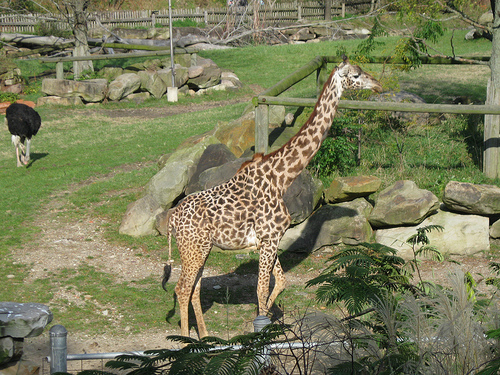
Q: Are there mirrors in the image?
A: No, there are no mirrors.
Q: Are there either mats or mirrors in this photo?
A: No, there are no mirrors or mats.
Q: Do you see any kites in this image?
A: No, there are no kites.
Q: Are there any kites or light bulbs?
A: No, there are no kites or light bulbs.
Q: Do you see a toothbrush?
A: No, there are no toothbrushes.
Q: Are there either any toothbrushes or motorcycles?
A: No, there are no toothbrushes or motorcycles.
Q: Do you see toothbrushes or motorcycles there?
A: No, there are no toothbrushes or motorcycles.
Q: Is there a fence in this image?
A: Yes, there is a fence.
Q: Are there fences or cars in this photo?
A: Yes, there is a fence.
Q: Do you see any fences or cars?
A: Yes, there is a fence.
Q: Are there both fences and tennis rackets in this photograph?
A: No, there is a fence but no rackets.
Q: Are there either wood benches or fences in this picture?
A: Yes, there is a wood fence.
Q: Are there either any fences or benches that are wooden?
A: Yes, the fence is wooden.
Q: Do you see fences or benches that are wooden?
A: Yes, the fence is wooden.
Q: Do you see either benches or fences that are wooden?
A: Yes, the fence is wooden.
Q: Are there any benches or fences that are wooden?
A: Yes, the fence is wooden.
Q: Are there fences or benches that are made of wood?
A: Yes, the fence is made of wood.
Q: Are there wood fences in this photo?
A: Yes, there is a wood fence.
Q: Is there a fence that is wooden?
A: Yes, there is a fence that is wooden.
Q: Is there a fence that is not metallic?
A: Yes, there is a wooden fence.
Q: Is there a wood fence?
A: Yes, there is a fence that is made of wood.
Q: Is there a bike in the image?
A: No, there are no bikes.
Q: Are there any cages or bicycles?
A: No, there are no bicycles or cages.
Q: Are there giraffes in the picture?
A: Yes, there is a giraffe.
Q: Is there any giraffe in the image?
A: Yes, there is a giraffe.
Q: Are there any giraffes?
A: Yes, there is a giraffe.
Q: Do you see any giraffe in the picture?
A: Yes, there is a giraffe.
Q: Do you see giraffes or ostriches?
A: Yes, there is a giraffe.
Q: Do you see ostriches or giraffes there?
A: Yes, there is a giraffe.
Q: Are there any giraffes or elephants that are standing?
A: Yes, the giraffe is standing.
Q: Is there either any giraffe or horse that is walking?
A: Yes, the giraffe is walking.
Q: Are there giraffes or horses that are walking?
A: Yes, the giraffe is walking.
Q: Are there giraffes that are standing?
A: Yes, there is a giraffe that is standing.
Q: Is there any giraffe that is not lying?
A: Yes, there is a giraffe that is standing.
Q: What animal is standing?
A: The animal is a giraffe.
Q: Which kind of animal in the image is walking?
A: The animal is a giraffe.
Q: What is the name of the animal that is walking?
A: The animal is a giraffe.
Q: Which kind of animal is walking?
A: The animal is a giraffe.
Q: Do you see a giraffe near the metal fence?
A: Yes, there is a giraffe near the fence.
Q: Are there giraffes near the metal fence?
A: Yes, there is a giraffe near the fence.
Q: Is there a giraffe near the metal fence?
A: Yes, there is a giraffe near the fence.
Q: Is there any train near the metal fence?
A: No, there is a giraffe near the fence.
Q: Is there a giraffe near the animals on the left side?
A: Yes, there is a giraffe near the animals.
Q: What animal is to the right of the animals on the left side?
A: The animal is a giraffe.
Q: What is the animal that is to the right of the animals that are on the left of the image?
A: The animal is a giraffe.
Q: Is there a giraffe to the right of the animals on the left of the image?
A: Yes, there is a giraffe to the right of the animals.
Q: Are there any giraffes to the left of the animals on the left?
A: No, the giraffe is to the right of the animals.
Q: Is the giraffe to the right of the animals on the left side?
A: Yes, the giraffe is to the right of the animals.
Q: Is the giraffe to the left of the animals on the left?
A: No, the giraffe is to the right of the animals.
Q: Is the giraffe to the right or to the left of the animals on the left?
A: The giraffe is to the right of the animals.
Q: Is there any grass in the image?
A: Yes, there is grass.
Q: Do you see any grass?
A: Yes, there is grass.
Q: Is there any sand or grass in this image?
A: Yes, there is grass.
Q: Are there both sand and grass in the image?
A: No, there is grass but no sand.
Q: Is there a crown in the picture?
A: No, there are no crowns.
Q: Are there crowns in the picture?
A: No, there are no crowns.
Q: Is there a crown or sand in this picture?
A: No, there are no crowns or sand.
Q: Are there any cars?
A: No, there are no cars.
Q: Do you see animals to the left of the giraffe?
A: Yes, there are animals to the left of the giraffe.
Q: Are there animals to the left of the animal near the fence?
A: Yes, there are animals to the left of the giraffe.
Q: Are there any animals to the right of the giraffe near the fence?
A: No, the animals are to the left of the giraffe.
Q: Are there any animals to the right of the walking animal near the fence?
A: No, the animals are to the left of the giraffe.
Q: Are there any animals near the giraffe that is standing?
A: Yes, there are animals near the giraffe.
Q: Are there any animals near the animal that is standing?
A: Yes, there are animals near the giraffe.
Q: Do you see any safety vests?
A: No, there are no safety vests.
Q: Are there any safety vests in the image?
A: No, there are no safety vests.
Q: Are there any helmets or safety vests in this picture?
A: No, there are no safety vests or helmets.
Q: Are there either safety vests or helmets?
A: No, there are no safety vests or helmets.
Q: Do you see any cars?
A: No, there are no cars.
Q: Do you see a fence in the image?
A: Yes, there is a fence.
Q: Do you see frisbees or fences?
A: Yes, there is a fence.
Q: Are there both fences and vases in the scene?
A: No, there is a fence but no vases.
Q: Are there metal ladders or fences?
A: Yes, there is a metal fence.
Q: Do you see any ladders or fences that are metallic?
A: Yes, the fence is metallic.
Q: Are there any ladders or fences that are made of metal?
A: Yes, the fence is made of metal.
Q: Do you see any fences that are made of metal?
A: Yes, there is a fence that is made of metal.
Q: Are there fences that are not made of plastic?
A: Yes, there is a fence that is made of metal.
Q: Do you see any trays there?
A: No, there are no trays.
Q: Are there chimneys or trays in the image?
A: No, there are no trays or chimneys.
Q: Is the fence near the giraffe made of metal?
A: Yes, the fence is made of metal.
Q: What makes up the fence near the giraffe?
A: The fence is made of metal.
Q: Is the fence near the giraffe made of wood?
A: No, the fence is made of metal.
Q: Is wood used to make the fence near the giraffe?
A: No, the fence is made of metal.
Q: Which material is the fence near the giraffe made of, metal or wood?
A: The fence is made of metal.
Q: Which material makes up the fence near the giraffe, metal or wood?
A: The fence is made of metal.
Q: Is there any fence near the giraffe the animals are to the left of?
A: Yes, there is a fence near the giraffe.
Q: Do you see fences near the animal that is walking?
A: Yes, there is a fence near the giraffe.